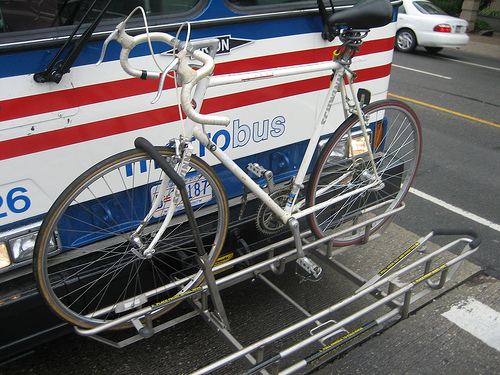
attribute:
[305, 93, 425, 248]
tire — red, black, round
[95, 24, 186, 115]
breaks — silver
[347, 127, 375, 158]
light — on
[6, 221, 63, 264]
light — off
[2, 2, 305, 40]
windshield — glass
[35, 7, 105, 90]
wiper — black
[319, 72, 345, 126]
schwinn — gray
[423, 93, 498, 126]
line — yellow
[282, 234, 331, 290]
petals — metal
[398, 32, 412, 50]
hubcap — silver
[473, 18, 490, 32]
grass — green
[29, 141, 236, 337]
front tire — yellow, black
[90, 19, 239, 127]
handle bars — white, pair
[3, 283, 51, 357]
bumper — black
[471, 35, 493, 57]
sidewalk — gray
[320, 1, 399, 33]
seat — black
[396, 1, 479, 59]
car — white, parked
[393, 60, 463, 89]
line — white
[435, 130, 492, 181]
road — black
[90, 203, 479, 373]
rack — silver, black, metal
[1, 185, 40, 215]
number — blue, identification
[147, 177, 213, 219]
plate — blue, license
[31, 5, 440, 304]
bike — white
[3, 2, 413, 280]
bus — blue, white, red, model, passenger, public, painted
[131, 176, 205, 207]
license plate — hidden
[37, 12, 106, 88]
windshield wiper — black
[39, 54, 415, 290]
bicycle — white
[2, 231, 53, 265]
headlights — lit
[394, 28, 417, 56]
tire — rear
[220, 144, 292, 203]
tube — white, top, down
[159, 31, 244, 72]
manufacturer — hidden